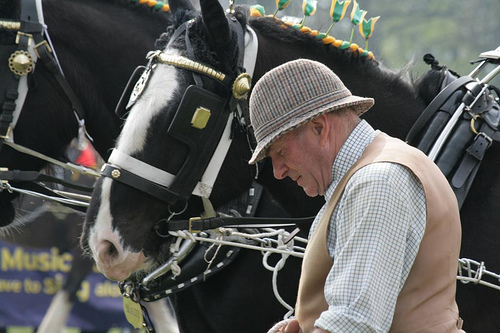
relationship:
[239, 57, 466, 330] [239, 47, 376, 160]
man wearing hat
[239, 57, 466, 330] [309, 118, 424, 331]
man wearing shirt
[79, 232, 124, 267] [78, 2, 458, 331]
nose belonging to horse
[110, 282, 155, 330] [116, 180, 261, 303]
yellow tag hanging from strap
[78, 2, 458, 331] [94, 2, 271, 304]
horse wearing harness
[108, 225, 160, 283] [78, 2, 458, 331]
mouth belonging to horse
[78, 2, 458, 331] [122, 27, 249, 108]
horse wearing something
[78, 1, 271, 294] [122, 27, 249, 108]
head wearing something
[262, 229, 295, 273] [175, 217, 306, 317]
knot on rope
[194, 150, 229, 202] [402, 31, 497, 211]
belt on sadle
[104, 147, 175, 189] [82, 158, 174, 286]
strap on nose